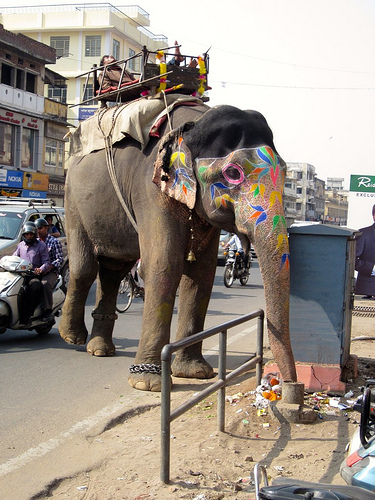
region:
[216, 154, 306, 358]
Elephant trunk is painted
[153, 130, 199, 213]
Ear of elephant is painted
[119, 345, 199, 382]
Chain around elephant ankle.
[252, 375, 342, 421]
Trash on the ground.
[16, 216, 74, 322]
People on the scooter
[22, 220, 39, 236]
The helmet is black.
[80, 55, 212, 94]
A person in a cart on top of elephant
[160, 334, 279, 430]
Railing by the garbage can.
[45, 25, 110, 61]
Window on the building.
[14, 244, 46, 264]
The shirt is purple.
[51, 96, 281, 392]
elephant standing inf ront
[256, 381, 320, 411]
trash on side of the road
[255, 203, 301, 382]
long grey trunk of elephant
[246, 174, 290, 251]
colors painted on elephant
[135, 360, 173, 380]
silver chains around ankle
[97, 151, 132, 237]
brown rope around elephant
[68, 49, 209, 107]
carrying contraption on top of elephant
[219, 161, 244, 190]
pink around eye of elephant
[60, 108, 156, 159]
white sheet on top of elephant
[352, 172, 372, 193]
green street sign by road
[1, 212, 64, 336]
Two men sitting on a motor bike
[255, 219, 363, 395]
Blue and red rectangular box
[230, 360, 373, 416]
Pile of trash on ground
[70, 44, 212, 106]
Man laying down in wooden basket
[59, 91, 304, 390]
Elephant with chain on front and back leg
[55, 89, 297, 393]
Elephant with brightly painted face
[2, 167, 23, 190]
White and blue sign with NOVA in white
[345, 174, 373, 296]
Sign with green and white top and man's picture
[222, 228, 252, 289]
Person riding a motorcycle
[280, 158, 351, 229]
Run down gray buildings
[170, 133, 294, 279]
the paint on the elephants face and ear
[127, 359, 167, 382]
a chain around the elephant's ankle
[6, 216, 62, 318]
people sitting on a scooter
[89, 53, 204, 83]
a man sleeping in the cart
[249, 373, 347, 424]
assorted trash on the ground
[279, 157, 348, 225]
some more building across the street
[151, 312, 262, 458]
a metal fence by the elephant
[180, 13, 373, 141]
the bright sunny sky above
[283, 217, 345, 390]
a big post next to the trunk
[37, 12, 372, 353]
an elephant chained up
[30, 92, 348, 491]
an elephant with a chain around its foot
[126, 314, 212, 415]
a chain around the foot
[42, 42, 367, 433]
an elephant with a carriage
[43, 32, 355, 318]
a carraige on an elephant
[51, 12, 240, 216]
a man in the carriage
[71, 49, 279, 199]
a man riding an elephant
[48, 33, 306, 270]
an elephant carrying a man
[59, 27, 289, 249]
an elephant with a man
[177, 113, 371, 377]
a painted elephant